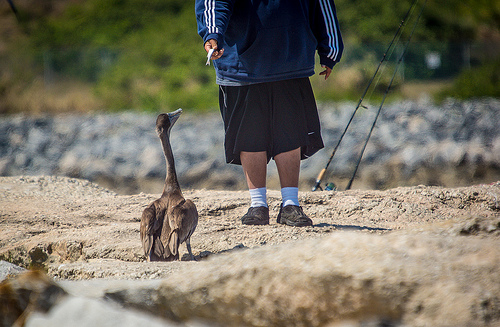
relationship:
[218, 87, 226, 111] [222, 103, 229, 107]
pocket has part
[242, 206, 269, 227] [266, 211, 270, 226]
shoe has edge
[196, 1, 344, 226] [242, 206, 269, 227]
person wearing shoe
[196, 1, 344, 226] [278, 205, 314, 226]
person wearing shoe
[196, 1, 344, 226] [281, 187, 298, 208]
person wearing sock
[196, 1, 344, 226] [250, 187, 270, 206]
person wearing sock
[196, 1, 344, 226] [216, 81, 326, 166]
person wearing shorts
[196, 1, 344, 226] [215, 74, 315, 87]
person wearing undershirt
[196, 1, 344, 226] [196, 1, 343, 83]
person wearing sweatshirt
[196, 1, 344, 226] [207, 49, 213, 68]
person holding fish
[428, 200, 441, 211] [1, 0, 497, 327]
dirt on ground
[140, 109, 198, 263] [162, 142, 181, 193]
duck has neck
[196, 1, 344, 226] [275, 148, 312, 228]
person has leg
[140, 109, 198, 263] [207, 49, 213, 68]
duck about to eat fish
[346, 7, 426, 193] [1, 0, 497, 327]
fishing gear set in ground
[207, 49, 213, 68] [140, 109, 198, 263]
fish about to be fed to duck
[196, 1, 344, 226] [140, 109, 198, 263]
person feeding duck